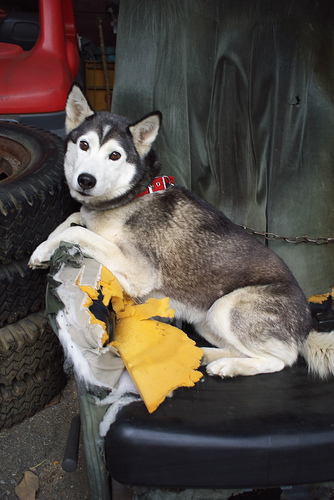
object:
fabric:
[43, 240, 204, 416]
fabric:
[307, 286, 333, 305]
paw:
[27, 258, 39, 271]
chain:
[237, 224, 334, 247]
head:
[63, 85, 162, 204]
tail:
[300, 326, 334, 384]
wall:
[159, 24, 332, 175]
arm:
[61, 412, 81, 472]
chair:
[44, 0, 333, 499]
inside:
[74, 265, 204, 412]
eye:
[109, 150, 121, 161]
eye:
[79, 140, 89, 151]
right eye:
[78, 141, 87, 150]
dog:
[26, 68, 333, 382]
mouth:
[77, 173, 96, 190]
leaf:
[10, 468, 43, 499]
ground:
[0, 425, 94, 499]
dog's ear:
[128, 109, 163, 160]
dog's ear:
[64, 81, 94, 136]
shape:
[204, 49, 271, 247]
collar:
[135, 175, 174, 198]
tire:
[0, 120, 75, 266]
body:
[81, 176, 312, 365]